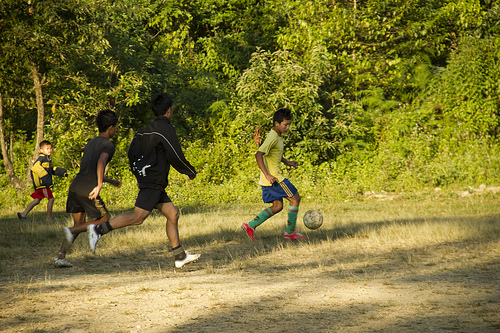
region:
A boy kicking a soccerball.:
[237, 105, 328, 255]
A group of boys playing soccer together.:
[12, 80, 354, 280]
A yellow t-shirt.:
[255, 130, 281, 181]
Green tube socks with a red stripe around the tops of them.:
[245, 205, 300, 235]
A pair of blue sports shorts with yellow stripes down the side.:
[255, 175, 295, 196]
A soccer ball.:
[300, 207, 325, 229]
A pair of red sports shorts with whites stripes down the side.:
[29, 187, 56, 201]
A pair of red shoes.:
[239, 225, 306, 247]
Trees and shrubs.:
[0, 0, 496, 203]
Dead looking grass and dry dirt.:
[3, 200, 498, 330]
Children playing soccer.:
[47, 90, 324, 265]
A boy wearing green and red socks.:
[248, 197, 300, 224]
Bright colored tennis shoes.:
[235, 220, 310, 246]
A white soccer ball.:
[297, 200, 324, 230]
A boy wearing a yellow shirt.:
[250, 115, 290, 185]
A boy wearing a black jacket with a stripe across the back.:
[120, 95, 195, 156]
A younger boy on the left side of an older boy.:
[5, 110, 120, 215]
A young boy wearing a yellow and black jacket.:
[27, 140, 57, 182]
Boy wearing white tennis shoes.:
[165, 247, 210, 267]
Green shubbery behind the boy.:
[206, 71, 406, 166]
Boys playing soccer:
[13, 90, 328, 270]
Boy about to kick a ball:
[240, 105, 330, 244]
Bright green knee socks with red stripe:
[240, 200, 307, 247]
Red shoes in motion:
[240, 223, 310, 244]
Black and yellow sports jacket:
[28, 150, 70, 187]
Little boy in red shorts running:
[14, 135, 66, 225]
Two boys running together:
[53, 87, 205, 272]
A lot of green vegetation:
[303, 22, 499, 208]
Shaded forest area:
[1, 1, 89, 141]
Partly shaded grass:
[323, 197, 497, 257]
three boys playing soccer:
[50, 78, 384, 298]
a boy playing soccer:
[226, 78, 335, 258]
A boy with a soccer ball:
[236, 76, 339, 272]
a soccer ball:
[289, 194, 350, 253]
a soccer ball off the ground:
[258, 189, 364, 247]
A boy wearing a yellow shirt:
[228, 77, 348, 273]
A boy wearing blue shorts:
[241, 87, 319, 284]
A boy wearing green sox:
[241, 90, 317, 265]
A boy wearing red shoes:
[237, 88, 314, 263]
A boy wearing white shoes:
[104, 97, 205, 290]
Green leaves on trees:
[5, 6, 495, 103]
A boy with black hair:
[261, 102, 306, 149]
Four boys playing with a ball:
[21, 93, 341, 279]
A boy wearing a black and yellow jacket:
[22, 134, 67, 192]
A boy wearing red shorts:
[23, 136, 61, 216]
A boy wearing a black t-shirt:
[65, 100, 122, 208]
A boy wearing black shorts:
[62, 103, 123, 234]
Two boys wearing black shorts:
[59, 88, 211, 240]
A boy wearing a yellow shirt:
[240, 99, 316, 190]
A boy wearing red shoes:
[218, 218, 312, 254]